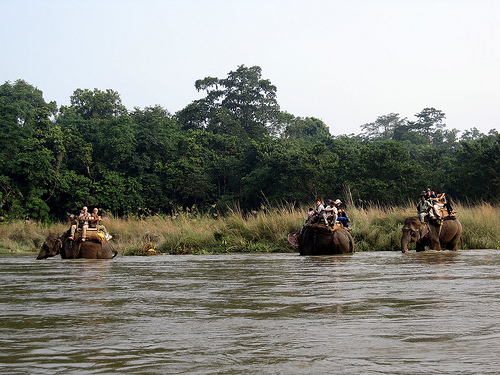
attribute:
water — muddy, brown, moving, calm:
[2, 260, 499, 372]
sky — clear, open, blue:
[1, 0, 499, 77]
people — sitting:
[300, 195, 348, 230]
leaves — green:
[22, 123, 280, 190]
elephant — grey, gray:
[400, 213, 466, 254]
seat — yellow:
[430, 211, 459, 220]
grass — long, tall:
[114, 217, 287, 245]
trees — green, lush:
[12, 129, 487, 198]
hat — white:
[81, 206, 89, 213]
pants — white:
[421, 211, 429, 222]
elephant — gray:
[40, 228, 107, 260]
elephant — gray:
[296, 220, 353, 258]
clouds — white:
[19, 8, 121, 43]